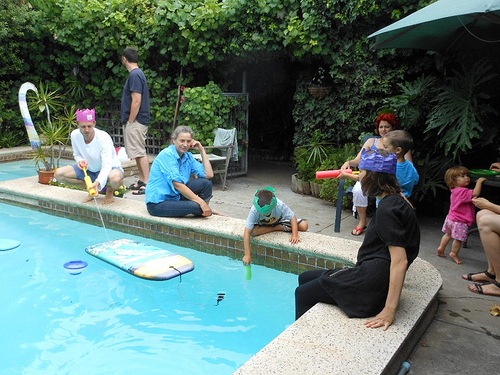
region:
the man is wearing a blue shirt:
[147, 142, 205, 201]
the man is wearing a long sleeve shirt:
[145, 147, 205, 198]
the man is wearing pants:
[146, 181, 214, 217]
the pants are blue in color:
[146, 178, 212, 220]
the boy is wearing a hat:
[251, 186, 278, 214]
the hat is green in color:
[252, 187, 275, 213]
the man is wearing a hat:
[361, 141, 397, 174]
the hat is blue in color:
[358, 145, 395, 171]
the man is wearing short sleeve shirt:
[353, 195, 421, 295]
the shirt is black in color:
[345, 195, 424, 303]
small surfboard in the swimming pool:
[72, 235, 199, 294]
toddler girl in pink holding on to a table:
[437, 162, 484, 259]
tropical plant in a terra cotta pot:
[24, 85, 76, 191]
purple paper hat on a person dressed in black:
[359, 144, 399, 176]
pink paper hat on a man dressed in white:
[70, 107, 102, 123]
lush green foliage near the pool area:
[44, 0, 334, 57]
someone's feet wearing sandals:
[460, 263, 498, 299]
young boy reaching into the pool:
[238, 187, 318, 278]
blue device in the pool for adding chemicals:
[56, 259, 91, 282]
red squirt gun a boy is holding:
[312, 167, 354, 182]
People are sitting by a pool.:
[55, 43, 498, 336]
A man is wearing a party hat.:
[72, 102, 97, 124]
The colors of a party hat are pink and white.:
[72, 104, 98, 125]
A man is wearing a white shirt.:
[65, 124, 119, 196]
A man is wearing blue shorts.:
[67, 160, 126, 185]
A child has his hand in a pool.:
[238, 183, 310, 278]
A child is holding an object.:
[312, 125, 421, 214]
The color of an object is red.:
[312, 163, 354, 183]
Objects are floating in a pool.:
[0, 229, 197, 287]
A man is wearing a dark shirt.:
[115, 63, 154, 130]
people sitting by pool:
[59, 97, 414, 344]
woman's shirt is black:
[336, 203, 422, 325]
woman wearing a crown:
[356, 143, 401, 173]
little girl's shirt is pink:
[441, 180, 477, 226]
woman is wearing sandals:
[461, 257, 498, 306]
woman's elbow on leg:
[143, 125, 224, 223]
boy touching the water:
[231, 185, 312, 268]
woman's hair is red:
[368, 112, 402, 141]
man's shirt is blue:
[112, 63, 157, 133]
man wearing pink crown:
[69, 103, 103, 138]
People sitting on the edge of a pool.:
[0, 45, 497, 370]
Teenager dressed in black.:
[295, 145, 415, 335]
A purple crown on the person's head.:
[355, 140, 392, 171]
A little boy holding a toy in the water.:
[240, 185, 308, 285]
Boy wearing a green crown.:
[250, 185, 277, 215]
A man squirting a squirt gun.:
[55, 106, 124, 202]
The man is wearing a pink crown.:
[70, 107, 95, 122]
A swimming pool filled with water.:
[0, 145, 345, 370]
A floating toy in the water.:
[86, 235, 194, 280]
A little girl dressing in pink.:
[435, 165, 485, 266]